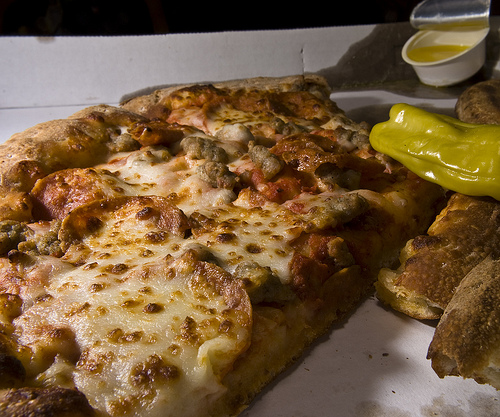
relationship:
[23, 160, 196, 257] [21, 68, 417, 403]
sausage on pizza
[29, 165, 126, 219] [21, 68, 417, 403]
pepperoni on pizza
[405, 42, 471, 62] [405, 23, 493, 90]
dipping sauce in container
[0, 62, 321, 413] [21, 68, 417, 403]
crust on pizza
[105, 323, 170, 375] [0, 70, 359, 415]
white gooey on pizza top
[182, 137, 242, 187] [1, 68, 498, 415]
sausage on a pizza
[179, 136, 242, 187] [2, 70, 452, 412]
sausage on top of pizza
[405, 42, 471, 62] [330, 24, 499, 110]
dipping sauce on box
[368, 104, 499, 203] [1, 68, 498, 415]
banana pepper on pizza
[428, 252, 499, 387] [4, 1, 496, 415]
crust on table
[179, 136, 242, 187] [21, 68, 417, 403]
sausage on pizza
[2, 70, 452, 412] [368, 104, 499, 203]
pizza and banana pepper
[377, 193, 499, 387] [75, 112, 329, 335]
crust of a pizza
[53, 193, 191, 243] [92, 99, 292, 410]
pepperoni on pizza